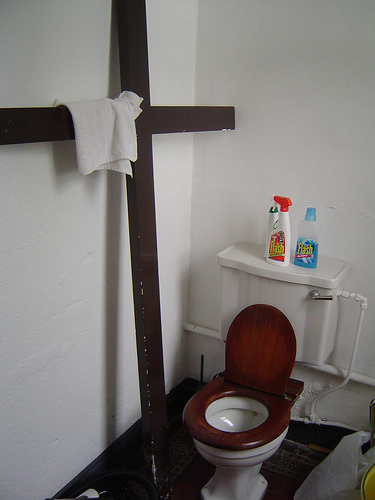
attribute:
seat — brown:
[186, 368, 291, 447]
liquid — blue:
[295, 241, 316, 267]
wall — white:
[19, 146, 133, 491]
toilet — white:
[183, 239, 352, 498]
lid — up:
[216, 303, 296, 397]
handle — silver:
[301, 286, 352, 306]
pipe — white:
[295, 268, 366, 419]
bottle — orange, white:
[265, 195, 292, 268]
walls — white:
[3, 1, 373, 494]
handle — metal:
[310, 289, 333, 302]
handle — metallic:
[309, 289, 333, 300]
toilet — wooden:
[164, 302, 312, 465]